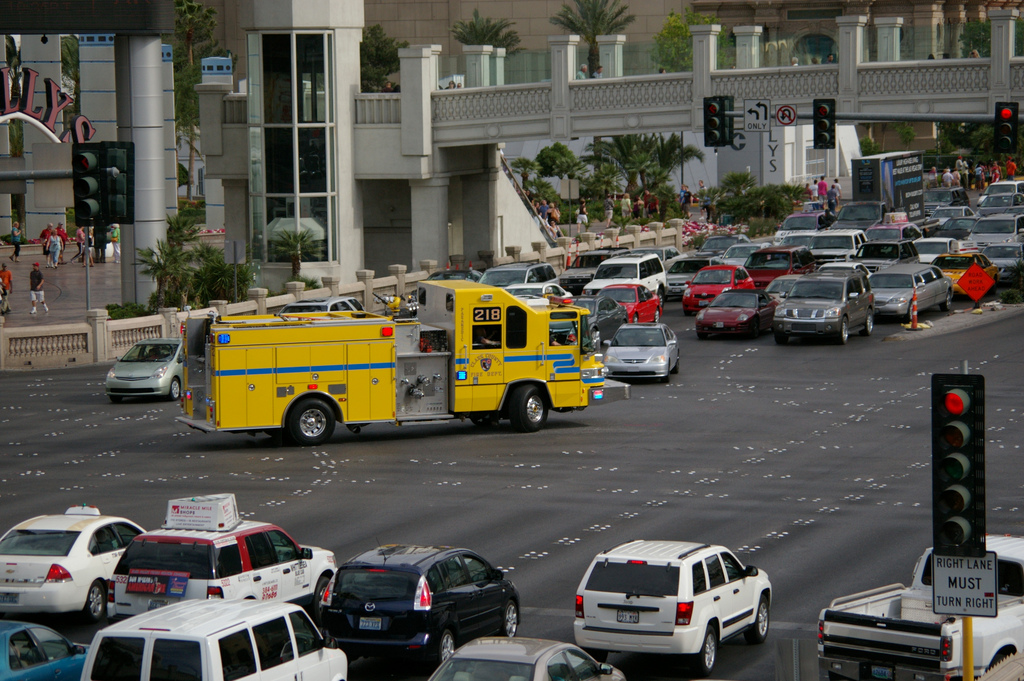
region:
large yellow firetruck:
[169, 287, 599, 433]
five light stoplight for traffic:
[931, 368, 988, 568]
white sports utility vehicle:
[577, 536, 778, 655]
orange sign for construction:
[954, 261, 993, 304]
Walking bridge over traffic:
[362, 15, 1023, 172]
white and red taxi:
[112, 492, 335, 642]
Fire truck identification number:
[473, 300, 506, 314]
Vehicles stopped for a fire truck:
[8, 170, 1023, 668]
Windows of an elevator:
[261, 33, 339, 261]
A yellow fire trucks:
[170, 277, 632, 437]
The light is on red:
[926, 374, 988, 556]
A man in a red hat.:
[26, 257, 49, 315]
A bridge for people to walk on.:
[199, 7, 1022, 184]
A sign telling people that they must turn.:
[932, 550, 1002, 617]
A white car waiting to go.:
[569, 535, 775, 666]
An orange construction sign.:
[958, 264, 994, 306]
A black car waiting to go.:
[313, 544, 523, 655]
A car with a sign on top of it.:
[113, 490, 336, 612]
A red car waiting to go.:
[682, 261, 758, 315]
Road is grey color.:
[427, 416, 922, 554]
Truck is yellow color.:
[177, 284, 610, 440]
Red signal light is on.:
[912, 375, 1023, 496]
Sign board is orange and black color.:
[941, 249, 995, 313]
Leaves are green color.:
[517, 134, 800, 261]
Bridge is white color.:
[416, 45, 1011, 147]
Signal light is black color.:
[51, 78, 1010, 560]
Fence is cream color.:
[16, 286, 267, 378]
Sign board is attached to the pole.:
[931, 548, 1020, 632]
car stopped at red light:
[573, 540, 773, 669]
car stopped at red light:
[427, 637, 621, 676]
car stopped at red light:
[320, 539, 522, 676]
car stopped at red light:
[103, 520, 339, 624]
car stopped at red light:
[0, 512, 154, 622]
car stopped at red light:
[5, 616, 99, 676]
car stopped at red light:
[692, 286, 783, 342]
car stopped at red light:
[776, 267, 878, 340]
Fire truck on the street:
[148, 246, 624, 469]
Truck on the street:
[161, 259, 618, 465]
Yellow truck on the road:
[147, 279, 622, 450]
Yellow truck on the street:
[173, 277, 614, 439]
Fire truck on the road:
[145, 268, 648, 465]